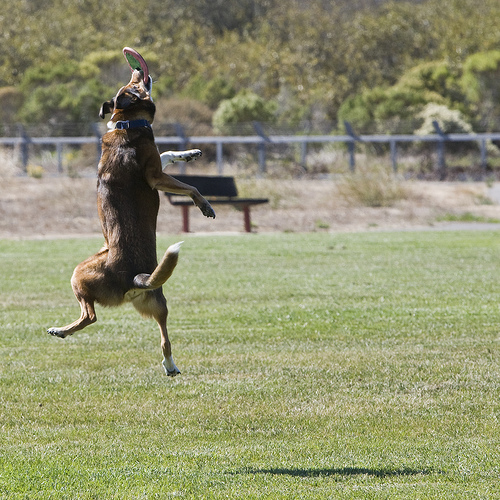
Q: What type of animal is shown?
A: Dog.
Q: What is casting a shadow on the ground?
A: Dog.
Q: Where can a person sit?
A: Bench.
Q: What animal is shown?
A: Dog.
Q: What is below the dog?
A: Grass.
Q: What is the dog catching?
A: A frisbee.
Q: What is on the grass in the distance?
A: Bench.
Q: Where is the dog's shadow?
A: On the grass.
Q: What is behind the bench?
A: A fence.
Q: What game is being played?
A: Frisbee.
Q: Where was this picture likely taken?
A: A park.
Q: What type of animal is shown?
A: Dog.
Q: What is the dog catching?
A: Frisbee.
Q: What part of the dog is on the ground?
A: Back right leg.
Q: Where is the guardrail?
A: Background.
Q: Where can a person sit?
A: Bench.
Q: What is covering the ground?
A: Grass.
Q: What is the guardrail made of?
A: Metal.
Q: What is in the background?
A: Trees.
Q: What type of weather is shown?
A: Sunny.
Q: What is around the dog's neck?
A: A collar.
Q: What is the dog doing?
A: Jumping.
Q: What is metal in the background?
A: A fence.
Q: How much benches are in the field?
A: One.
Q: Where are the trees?
A: Behind the metal fence.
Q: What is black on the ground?
A: The dog's shadow.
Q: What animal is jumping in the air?
A: A dog.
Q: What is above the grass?
A: A dog.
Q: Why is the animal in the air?
A: It's catching a frisbee.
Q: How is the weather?
A: Sunny.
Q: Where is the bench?
A: Next to the fence.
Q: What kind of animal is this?
A: A dog.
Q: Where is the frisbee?
A: In the dog's mouth.